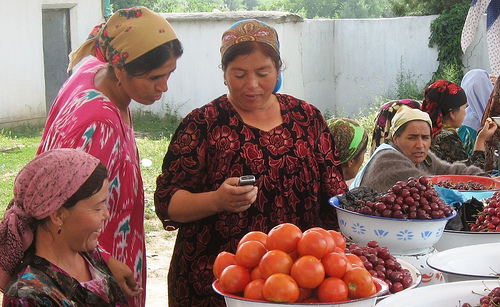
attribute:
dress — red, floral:
[153, 91, 350, 305]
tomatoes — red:
[211, 221, 377, 303]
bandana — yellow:
[85, 2, 177, 99]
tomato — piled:
[265, 220, 300, 254]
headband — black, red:
[422, 80, 467, 135]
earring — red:
[48, 212, 65, 247]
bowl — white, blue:
[329, 179, 433, 231]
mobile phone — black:
[238, 176, 255, 183]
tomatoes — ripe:
[206, 217, 384, 306]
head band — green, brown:
[422, 73, 469, 145]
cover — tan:
[373, 99, 446, 150]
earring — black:
[56, 225, 63, 234]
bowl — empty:
[424, 232, 499, 281]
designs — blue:
[336, 217, 352, 229]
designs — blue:
[347, 219, 367, 236]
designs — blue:
[372, 226, 396, 236]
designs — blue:
[394, 227, 414, 241]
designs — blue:
[418, 229, 432, 242]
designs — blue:
[433, 225, 445, 240]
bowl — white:
[328, 190, 455, 256]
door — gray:
[31, 3, 92, 124]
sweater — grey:
[337, 151, 425, 195]